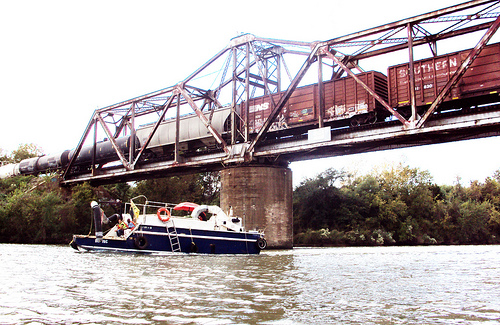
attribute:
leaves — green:
[372, 181, 413, 217]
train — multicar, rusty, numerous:
[0, 41, 499, 192]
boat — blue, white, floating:
[69, 193, 267, 258]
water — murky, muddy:
[1, 241, 500, 324]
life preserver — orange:
[156, 206, 172, 222]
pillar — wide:
[219, 167, 296, 252]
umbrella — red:
[174, 199, 202, 215]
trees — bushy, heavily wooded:
[0, 143, 500, 245]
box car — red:
[241, 69, 391, 141]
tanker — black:
[66, 132, 141, 170]